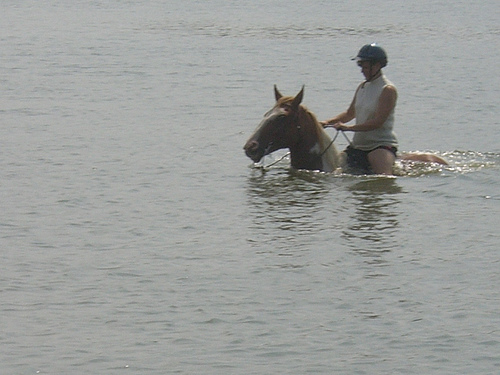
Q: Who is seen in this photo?
A: A horse and rider.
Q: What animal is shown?
A: Horse.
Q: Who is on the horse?
A: A woman.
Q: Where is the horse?
A: In the water.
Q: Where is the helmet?
A: On the woman.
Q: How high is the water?
A: Up to the horse's neck.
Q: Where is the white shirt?
A: On the woman.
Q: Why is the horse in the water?
A: To cross it.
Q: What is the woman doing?
A: Riding.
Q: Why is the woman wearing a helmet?
A: Safety.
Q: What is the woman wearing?
A: White shirt.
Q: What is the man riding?
A: A horse.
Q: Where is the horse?
A: In the water.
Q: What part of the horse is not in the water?
A: The head.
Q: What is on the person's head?
A: A helmet.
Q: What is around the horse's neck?
A: The bridal.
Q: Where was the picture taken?
A: The water.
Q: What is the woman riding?
A: A horse.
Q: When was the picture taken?
A: Daytime.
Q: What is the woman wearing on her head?
A: A helmet.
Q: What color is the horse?
A: Brown & white.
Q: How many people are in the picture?
A: One.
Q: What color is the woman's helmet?
A: Black.